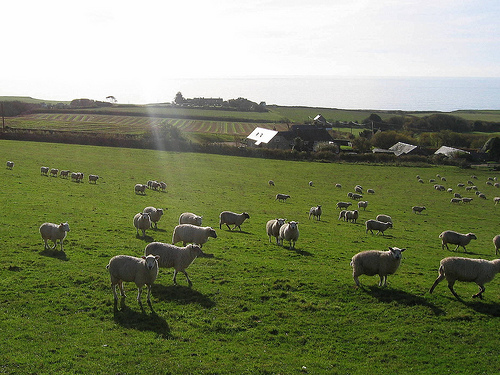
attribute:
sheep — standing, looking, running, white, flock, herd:
[36, 193, 235, 291]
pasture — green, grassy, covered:
[5, 137, 498, 374]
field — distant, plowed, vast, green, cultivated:
[26, 109, 295, 139]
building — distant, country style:
[246, 123, 288, 148]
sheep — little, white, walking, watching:
[39, 219, 72, 253]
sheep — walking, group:
[36, 160, 110, 182]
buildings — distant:
[383, 134, 489, 159]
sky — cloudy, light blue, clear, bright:
[6, 2, 498, 115]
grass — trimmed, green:
[227, 276, 498, 373]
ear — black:
[56, 221, 64, 228]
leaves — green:
[425, 116, 438, 119]